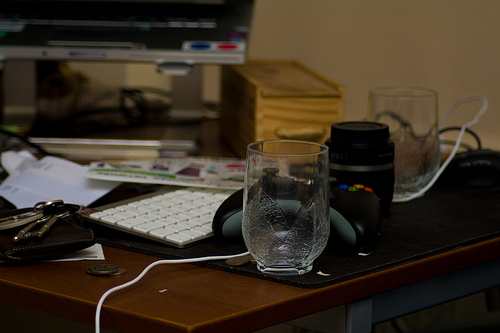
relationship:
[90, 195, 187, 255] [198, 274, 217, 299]
keyboard on table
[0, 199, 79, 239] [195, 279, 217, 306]
keys on table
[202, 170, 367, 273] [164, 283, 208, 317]
controller on table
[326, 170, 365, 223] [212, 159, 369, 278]
button on controller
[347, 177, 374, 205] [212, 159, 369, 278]
button on controller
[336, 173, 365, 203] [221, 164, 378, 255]
button on controller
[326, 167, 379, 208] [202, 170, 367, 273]
button on controller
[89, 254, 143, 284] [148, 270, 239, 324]
coins on table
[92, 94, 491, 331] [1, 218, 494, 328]
wire on desk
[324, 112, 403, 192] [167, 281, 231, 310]
camera lens on table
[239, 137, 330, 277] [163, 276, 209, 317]
glass on desk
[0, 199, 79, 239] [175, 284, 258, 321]
keys on desk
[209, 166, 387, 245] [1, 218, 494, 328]
xbox controller on desk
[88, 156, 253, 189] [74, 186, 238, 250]
paper partially on keyboard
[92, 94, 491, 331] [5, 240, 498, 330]
wire on desk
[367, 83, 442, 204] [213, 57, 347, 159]
glass next to box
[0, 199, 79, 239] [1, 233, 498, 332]
keys on table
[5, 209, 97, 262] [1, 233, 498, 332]
wallet on table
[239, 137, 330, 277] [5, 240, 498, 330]
glass on desk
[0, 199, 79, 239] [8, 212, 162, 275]
keys on top of a wallet